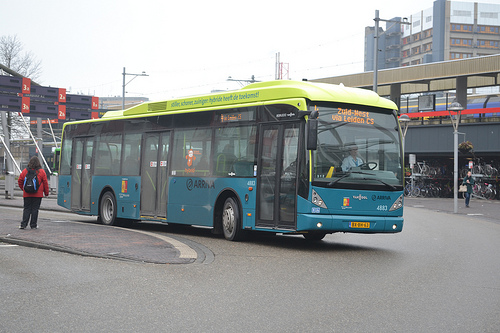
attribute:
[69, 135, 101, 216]
door — closed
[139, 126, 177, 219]
door — closed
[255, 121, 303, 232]
door — closed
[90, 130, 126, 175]
window — closed, tinted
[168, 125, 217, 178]
window — closed, tinted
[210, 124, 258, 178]
window — closed, tinted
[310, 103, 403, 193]
windshield — tinted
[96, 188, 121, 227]
tire — round, black, inflated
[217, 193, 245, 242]
tire — round, black, inflated